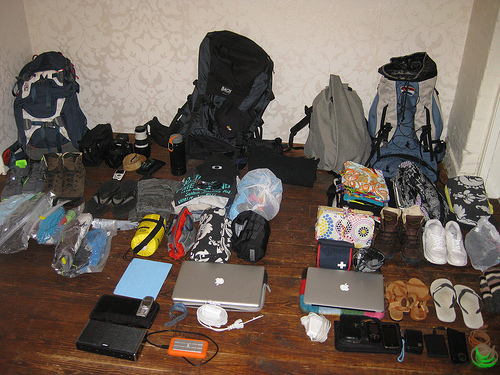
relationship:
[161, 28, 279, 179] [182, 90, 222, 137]
backpack with pocket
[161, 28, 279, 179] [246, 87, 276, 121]
backpack with pocket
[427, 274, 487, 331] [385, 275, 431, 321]
flip flops beside sandals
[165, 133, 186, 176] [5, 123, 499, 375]
bottle on floor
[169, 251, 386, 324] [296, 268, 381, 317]
two laptops next to striped knit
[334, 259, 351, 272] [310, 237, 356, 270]
sign is on case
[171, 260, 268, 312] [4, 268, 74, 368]
computer are on floor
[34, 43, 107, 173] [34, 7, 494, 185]
back pack against wall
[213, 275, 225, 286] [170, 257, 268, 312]
apple on computer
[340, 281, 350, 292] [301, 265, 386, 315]
apple on computer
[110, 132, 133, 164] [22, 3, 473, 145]
camera near wall